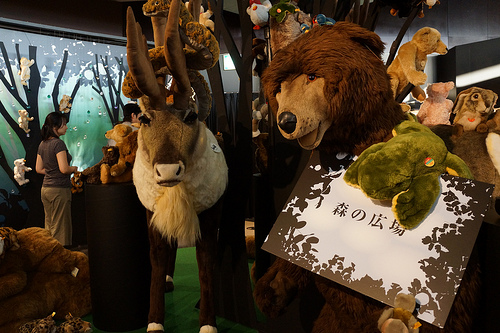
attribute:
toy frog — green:
[342, 120, 474, 230]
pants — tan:
[28, 180, 90, 242]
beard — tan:
[150, 178, 202, 244]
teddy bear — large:
[247, 19, 499, 331]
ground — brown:
[270, 108, 331, 154]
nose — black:
[277, 107, 302, 132]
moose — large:
[120, 0, 230, 330]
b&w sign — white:
[262, 141, 493, 328]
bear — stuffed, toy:
[272, 1, 455, 176]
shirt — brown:
[37, 134, 72, 186]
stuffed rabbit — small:
[450, 81, 498, 128]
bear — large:
[236, 30, 460, 330]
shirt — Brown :
[35, 135, 78, 188]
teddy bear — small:
[13, 107, 40, 132]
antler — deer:
[162, 3, 197, 104]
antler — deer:
[119, 6, 160, 108]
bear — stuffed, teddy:
[259, 29, 471, 330]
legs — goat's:
[141, 200, 220, 329]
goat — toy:
[118, 12, 228, 328]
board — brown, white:
[225, 174, 480, 329]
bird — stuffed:
[244, 0, 271, 29]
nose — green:
[351, 158, 411, 205]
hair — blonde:
[147, 177, 204, 249]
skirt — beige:
[35, 173, 96, 240]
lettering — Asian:
[331, 203, 417, 238]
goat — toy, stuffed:
[127, 0, 229, 331]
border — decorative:
[449, 227, 484, 287]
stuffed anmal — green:
[342, 115, 452, 225]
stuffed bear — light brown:
[381, 22, 461, 102]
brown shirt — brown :
[36, 139, 77, 188]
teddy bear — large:
[215, 20, 463, 330]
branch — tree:
[0, 100, 34, 135]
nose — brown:
[152, 157, 182, 187]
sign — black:
[250, 134, 498, 331]